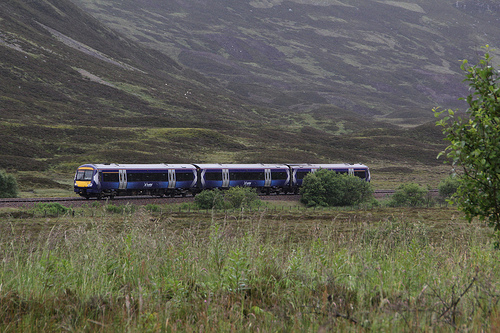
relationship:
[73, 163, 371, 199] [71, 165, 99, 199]
train has front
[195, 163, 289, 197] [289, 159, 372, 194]
car behind car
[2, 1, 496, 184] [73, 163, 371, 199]
hill behind train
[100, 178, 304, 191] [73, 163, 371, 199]
stripe on train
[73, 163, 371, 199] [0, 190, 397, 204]
train on tracks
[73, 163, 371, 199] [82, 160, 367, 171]
train has roof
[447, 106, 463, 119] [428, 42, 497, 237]
leaf on tree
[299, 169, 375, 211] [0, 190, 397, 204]
shrub near tracks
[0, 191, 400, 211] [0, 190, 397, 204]
gravel next to tracks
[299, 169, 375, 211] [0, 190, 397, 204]
shrub next to tracks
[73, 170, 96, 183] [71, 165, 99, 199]
window on front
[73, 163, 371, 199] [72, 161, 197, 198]
train has front car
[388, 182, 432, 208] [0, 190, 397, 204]
bush near tracks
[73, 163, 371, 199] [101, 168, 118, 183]
train has window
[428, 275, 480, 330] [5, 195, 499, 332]
branch on ground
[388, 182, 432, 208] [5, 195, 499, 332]
bush on ground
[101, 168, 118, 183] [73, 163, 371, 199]
window on train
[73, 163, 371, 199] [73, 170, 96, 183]
train has window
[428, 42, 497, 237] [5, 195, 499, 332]
tree on ground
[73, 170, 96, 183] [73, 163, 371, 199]
window on train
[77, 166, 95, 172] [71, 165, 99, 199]
stripe on front